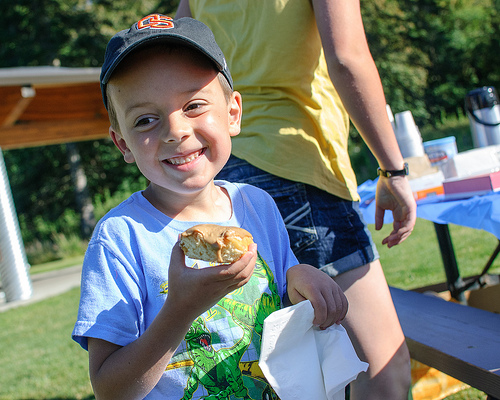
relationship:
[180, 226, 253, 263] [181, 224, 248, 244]
donut has frosting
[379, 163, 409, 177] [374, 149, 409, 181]
watch on wrist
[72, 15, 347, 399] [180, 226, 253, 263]
boy holds dessert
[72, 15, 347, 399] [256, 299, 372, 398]
boy holds napkin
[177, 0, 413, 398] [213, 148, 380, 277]
person wearing shorts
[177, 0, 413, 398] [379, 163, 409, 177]
person wearing watch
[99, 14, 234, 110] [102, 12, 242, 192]
hat on head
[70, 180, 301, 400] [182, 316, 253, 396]
shirt has dinosaur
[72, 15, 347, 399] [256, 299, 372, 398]
boy has napkin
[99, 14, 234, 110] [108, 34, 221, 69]
cap has bill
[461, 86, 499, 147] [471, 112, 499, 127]
thermos has handle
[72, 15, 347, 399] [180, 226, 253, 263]
boy has sandwich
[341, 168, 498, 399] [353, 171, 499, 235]
table has cover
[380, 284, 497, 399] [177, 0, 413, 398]
bench in front of woman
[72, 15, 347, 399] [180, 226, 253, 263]
child has doughnut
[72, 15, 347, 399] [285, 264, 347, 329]
boy has hand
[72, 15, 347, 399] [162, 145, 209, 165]
boy has smile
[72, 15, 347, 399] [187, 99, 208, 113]
boy has eye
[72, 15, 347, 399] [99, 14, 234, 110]
boy has cap